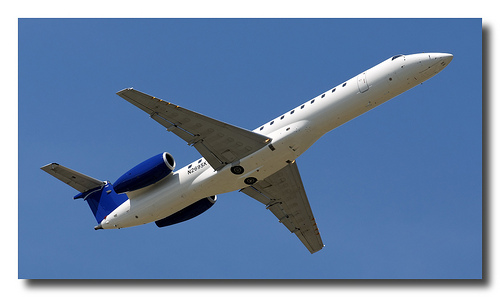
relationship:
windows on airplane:
[254, 77, 351, 132] [36, 50, 456, 254]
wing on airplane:
[40, 148, 128, 235] [36, 50, 456, 254]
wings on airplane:
[109, 81, 275, 172] [36, 50, 456, 254]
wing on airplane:
[231, 147, 340, 254] [36, 50, 456, 254]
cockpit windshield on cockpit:
[382, 38, 409, 61] [385, 44, 416, 66]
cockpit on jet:
[385, 44, 416, 66] [55, 36, 469, 251]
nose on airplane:
[400, 45, 459, 82] [36, 41, 453, 254]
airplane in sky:
[36, 41, 453, 254] [19, 17, 480, 279]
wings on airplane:
[104, 81, 311, 181] [36, 50, 456, 254]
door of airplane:
[352, 73, 375, 97] [36, 41, 453, 254]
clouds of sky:
[344, 132, 460, 249] [330, 127, 482, 279]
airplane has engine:
[36, 50, 456, 254] [105, 143, 181, 197]